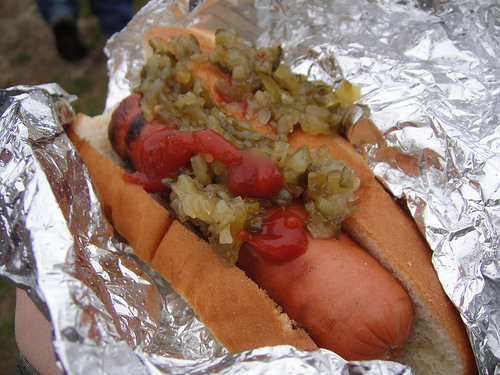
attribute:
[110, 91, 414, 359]
hotdog — on tin foil, pink, burnt, on bun, on foil, in bun, grilled, with condiments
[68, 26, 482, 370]
bun — brown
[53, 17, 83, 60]
shoe — in background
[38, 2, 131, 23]
pants — in background, blue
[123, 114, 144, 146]
burn mark — on hotdog, on hot dog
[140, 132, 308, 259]
ketchup — red, on hotdog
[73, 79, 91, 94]
grass — on ground, in background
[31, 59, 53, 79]
dirt — on ground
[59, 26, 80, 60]
sole — black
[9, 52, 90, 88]
spots — green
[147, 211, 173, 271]
groove — small, in bun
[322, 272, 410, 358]
edge — pink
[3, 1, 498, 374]
foil — wrinkled, shiny, large, aluminum, with hotdog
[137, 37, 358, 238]
radish — on hotdog, green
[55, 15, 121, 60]
feet — in background, dark color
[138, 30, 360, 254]
toppings — on hotdog, diced onion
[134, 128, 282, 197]
ketchup squirt — large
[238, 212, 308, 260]
ketchup squirt — small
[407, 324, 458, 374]
bread — white, under hotdog